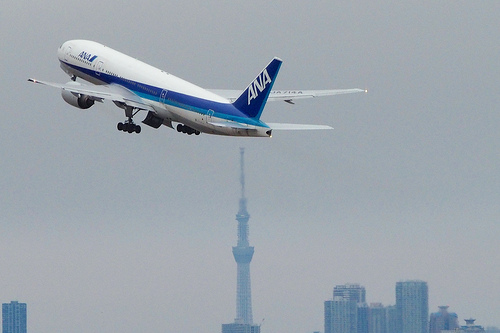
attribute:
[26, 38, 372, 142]
plane — flying, white, striped, taking off, airborne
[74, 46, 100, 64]
logo — ana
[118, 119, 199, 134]
wheels — down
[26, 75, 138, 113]
wing — white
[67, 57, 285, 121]
stripes — blue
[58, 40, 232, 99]
top — white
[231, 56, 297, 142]
tail — blue, white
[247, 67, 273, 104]
ana — white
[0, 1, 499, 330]
sky — hazy